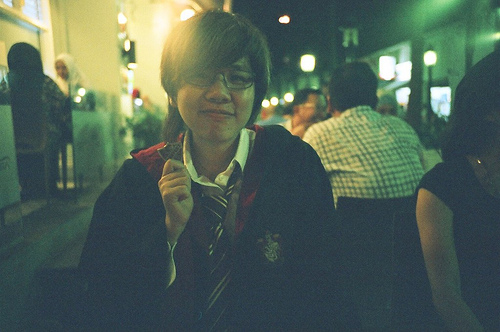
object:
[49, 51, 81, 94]
scarf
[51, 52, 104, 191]
woman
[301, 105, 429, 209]
shirt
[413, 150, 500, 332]
shirt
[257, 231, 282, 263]
emblem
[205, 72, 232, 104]
small nose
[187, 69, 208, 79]
brown eye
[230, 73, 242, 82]
eye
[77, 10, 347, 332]
man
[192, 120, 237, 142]
chin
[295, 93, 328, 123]
face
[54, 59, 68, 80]
face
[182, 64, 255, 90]
framed eye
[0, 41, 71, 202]
person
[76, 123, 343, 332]
cloak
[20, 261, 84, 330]
chair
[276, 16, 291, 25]
street lights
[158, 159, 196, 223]
woman hand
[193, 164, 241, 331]
tie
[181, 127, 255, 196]
shirt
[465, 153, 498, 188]
necklace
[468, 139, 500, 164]
neck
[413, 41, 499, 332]
woman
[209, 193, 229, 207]
stripe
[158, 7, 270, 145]
hair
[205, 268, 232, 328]
striped pattern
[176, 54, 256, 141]
face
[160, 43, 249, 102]
bangs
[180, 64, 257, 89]
eye glasses